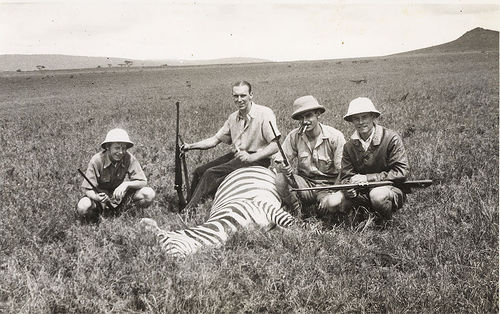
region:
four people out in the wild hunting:
[71, 80, 412, 255]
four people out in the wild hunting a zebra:
[76, 84, 423, 234]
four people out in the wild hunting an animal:
[79, 67, 421, 236]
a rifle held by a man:
[174, 100, 189, 201]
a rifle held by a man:
[290, 178, 438, 186]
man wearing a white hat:
[293, 97, 330, 114]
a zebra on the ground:
[157, 167, 274, 264]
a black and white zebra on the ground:
[144, 164, 277, 268]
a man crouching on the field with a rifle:
[74, 127, 154, 213]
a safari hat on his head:
[291, 95, 325, 116]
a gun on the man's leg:
[290, 175, 430, 191]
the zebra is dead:
[148, 165, 283, 265]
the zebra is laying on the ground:
[150, 167, 294, 264]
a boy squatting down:
[73, 130, 153, 220]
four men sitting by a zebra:
[71, 78, 422, 249]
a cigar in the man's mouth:
[300, 123, 310, 135]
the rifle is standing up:
[173, 100, 185, 205]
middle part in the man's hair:
[238, 78, 243, 86]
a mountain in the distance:
[418, 28, 498, 52]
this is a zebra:
[111, 161, 301, 271]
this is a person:
[334, 79, 416, 229]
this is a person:
[263, 90, 356, 230]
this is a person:
[188, 58, 299, 179]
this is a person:
[59, 127, 149, 218]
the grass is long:
[248, 250, 305, 305]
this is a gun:
[282, 172, 435, 208]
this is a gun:
[265, 109, 329, 241]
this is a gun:
[141, 84, 216, 214]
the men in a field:
[76, 80, 409, 227]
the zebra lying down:
[139, 167, 339, 265]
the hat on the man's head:
[342, 97, 380, 121]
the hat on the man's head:
[290, 95, 325, 120]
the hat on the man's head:
[100, 128, 134, 149]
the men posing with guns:
[77, 79, 432, 224]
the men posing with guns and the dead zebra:
[77, 80, 432, 265]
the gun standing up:
[173, 100, 190, 212]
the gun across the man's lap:
[290, 179, 433, 191]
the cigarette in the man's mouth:
[302, 123, 307, 132]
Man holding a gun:
[60, 107, 149, 212]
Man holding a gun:
[336, 100, 403, 233]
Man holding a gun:
[283, 80, 333, 234]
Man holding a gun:
[142, 79, 282, 189]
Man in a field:
[63, 108, 155, 220]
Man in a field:
[196, 58, 275, 171]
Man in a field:
[272, 66, 343, 218]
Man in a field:
[324, 79, 454, 231]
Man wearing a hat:
[330, 86, 390, 223]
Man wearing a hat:
[283, 76, 335, 208]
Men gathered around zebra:
[71, 75, 426, 233]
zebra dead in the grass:
[123, 164, 344, 269]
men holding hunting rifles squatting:
[77, 79, 434, 229]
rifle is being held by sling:
[171, 99, 192, 217]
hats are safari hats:
[102, 94, 380, 153]